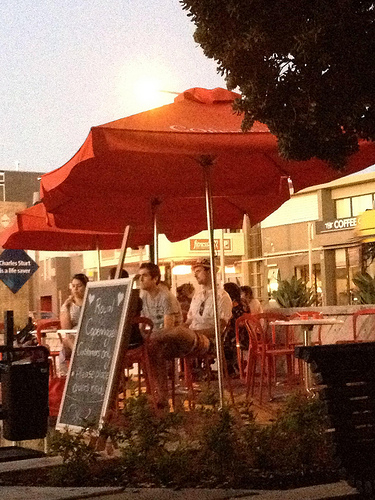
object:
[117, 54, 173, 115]
glare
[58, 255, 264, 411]
patrons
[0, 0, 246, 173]
sky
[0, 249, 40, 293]
sign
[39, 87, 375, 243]
canopy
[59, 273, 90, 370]
friend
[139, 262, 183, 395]
friend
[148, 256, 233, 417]
friend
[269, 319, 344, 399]
table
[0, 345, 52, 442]
garbage can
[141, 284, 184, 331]
t-shirt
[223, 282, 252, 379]
women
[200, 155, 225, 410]
stand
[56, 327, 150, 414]
restaurant table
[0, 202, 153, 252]
umbrella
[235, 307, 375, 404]
chairs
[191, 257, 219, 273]
hat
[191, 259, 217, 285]
head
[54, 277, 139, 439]
chalkboard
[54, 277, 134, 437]
menu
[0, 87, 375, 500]
restaurant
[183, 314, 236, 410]
chairs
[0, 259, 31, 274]
writing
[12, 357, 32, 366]
trash